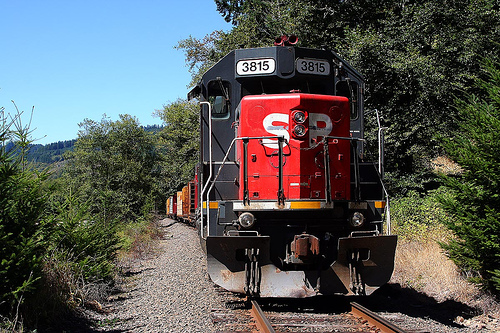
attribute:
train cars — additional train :
[162, 172, 199, 225]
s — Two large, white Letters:
[261, 113, 295, 160]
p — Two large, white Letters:
[306, 108, 331, 147]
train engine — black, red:
[205, 56, 362, 206]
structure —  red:
[236, 92, 366, 202]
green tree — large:
[432, 36, 499, 300]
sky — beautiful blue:
[53, 25, 150, 99]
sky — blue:
[2, 0, 239, 145]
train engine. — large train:
[192, 36, 401, 302]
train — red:
[183, 40, 405, 297]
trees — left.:
[5, 114, 140, 318]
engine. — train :
[184, 50, 399, 310]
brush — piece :
[354, 104, 396, 224]